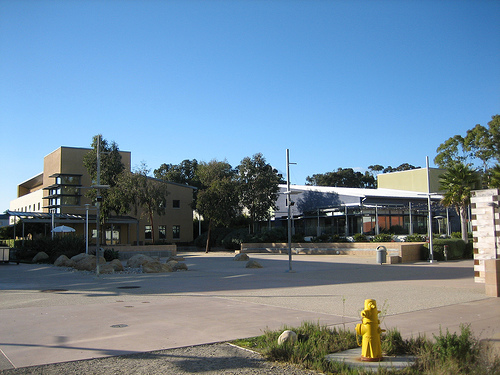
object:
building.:
[0, 94, 500, 321]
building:
[265, 183, 471, 243]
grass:
[298, 327, 335, 368]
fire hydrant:
[354, 298, 387, 362]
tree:
[83, 133, 169, 243]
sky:
[179, 35, 429, 118]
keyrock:
[142, 259, 164, 272]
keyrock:
[53, 253, 77, 267]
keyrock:
[128, 252, 149, 265]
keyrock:
[166, 261, 189, 272]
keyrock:
[165, 254, 185, 262]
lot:
[0, 251, 499, 375]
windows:
[3, 161, 183, 241]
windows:
[265, 195, 455, 240]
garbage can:
[376, 245, 388, 265]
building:
[1, 146, 198, 262]